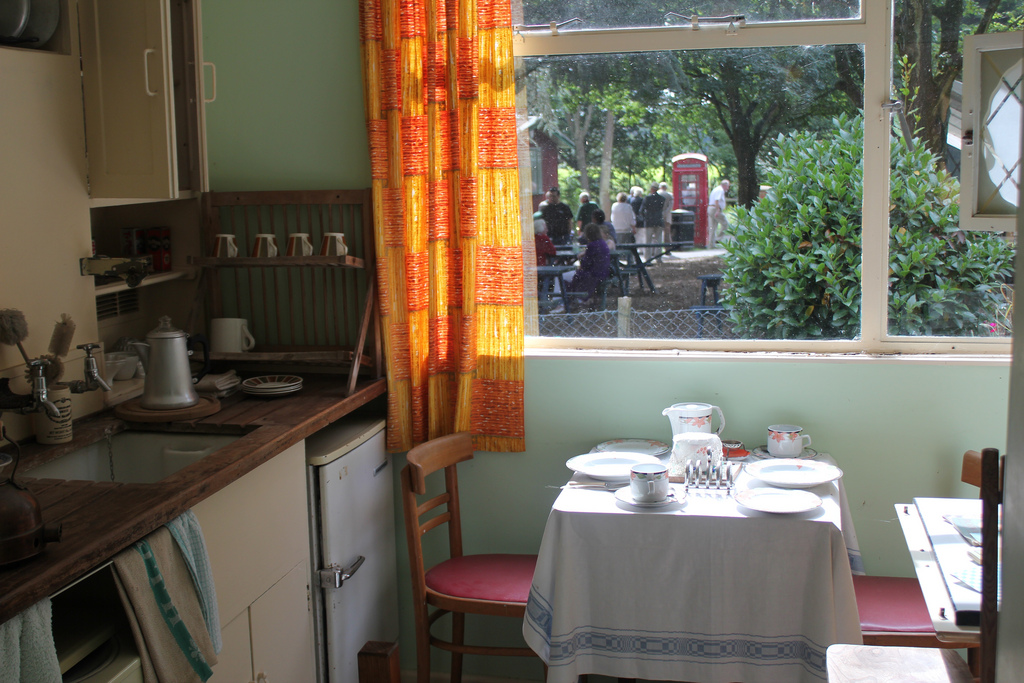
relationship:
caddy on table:
[688, 455, 728, 490] [530, 436, 863, 679]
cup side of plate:
[630, 464, 669, 503] [565, 448, 672, 488]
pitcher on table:
[668, 397, 721, 456] [530, 436, 863, 679]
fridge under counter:
[309, 418, 402, 682] [14, 349, 404, 658]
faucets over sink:
[25, 347, 95, 417] [23, 407, 250, 509]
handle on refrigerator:
[318, 556, 370, 587] [308, 414, 417, 680]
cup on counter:
[128, 316, 199, 410] [10, 354, 391, 623]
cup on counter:
[211, 310, 255, 358] [5, 358, 433, 642]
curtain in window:
[364, 1, 537, 473] [507, 6, 1019, 361]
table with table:
[528, 459, 855, 680] [528, 446, 867, 682]